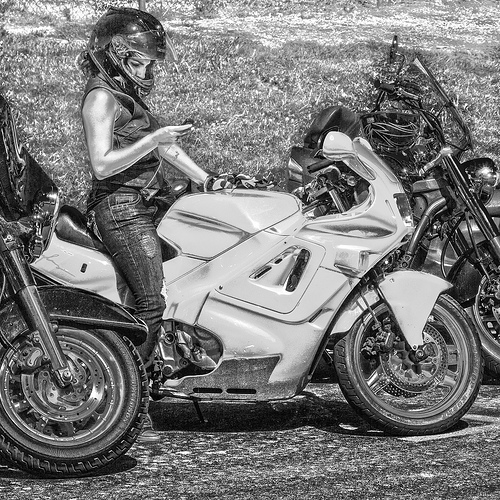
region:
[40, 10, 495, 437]
a woman sitting on a motorcycle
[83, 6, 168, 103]
a helmet on a woman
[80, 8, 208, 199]
a woman looking at a cellphone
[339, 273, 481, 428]
the front wheel of a motorcycle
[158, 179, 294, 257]
the gas tank of a motorcycle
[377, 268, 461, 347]
the fender of a motorcycle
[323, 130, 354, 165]
the mirror of a motorcycle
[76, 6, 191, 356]
a woman wearing jeans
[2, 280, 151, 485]
the front wheel of a motocycle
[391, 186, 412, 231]
the headlight of a motorcycle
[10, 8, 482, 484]
woman sitting on a motorcycle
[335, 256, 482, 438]
front tire of a motorbike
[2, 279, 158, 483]
back tire of a motorbike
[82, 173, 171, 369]
woman's leg in jeans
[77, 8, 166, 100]
woman wearing a helmet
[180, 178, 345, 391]
right side of the body of a motorbike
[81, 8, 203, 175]
a woman holding a cellphone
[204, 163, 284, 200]
woman's gloves for riding a motorcycle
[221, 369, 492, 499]
motorbike parking space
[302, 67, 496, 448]
front part of two different motorbikes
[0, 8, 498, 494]
The photo is in black and white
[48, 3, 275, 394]
A woman in the foreground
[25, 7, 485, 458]
Woman is on a sports bike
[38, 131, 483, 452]
A side view of a sports bike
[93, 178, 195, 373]
Woman is wearing jeans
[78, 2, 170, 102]
Woman is wearing a helmet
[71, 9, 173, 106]
Woman head is looking down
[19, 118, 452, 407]
The sports bike is light colored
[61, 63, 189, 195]
Woman is wearing a sleeveless jacket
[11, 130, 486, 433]
The Sportsbike in the image is parked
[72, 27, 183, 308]
woman sitting on motorbike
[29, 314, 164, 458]
round tire of motorcycle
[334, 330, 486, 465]
round tire of motorcycle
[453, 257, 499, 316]
round tire of motorcycle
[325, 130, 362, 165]
rear view mirror on motorcycle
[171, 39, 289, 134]
grass growing by bikes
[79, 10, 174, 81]
helmet on woman's head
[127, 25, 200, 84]
glass visor on helmet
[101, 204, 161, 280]
denim jeans on rider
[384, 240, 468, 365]
wheel guard on top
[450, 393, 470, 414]
the front tire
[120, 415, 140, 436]
front tire of the motorcycle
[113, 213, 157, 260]
women is wearing jeans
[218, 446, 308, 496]
the ground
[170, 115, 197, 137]
the women is holding an object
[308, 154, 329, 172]
handle bar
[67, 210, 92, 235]
the seat on the motorcycle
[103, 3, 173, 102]
the women is wearing a helmet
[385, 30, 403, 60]
a mirror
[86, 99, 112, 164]
the womens arm